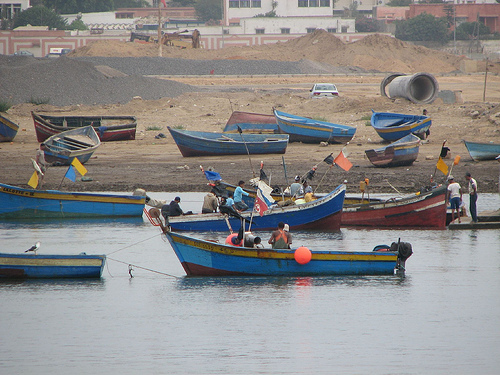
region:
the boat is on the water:
[158, 223, 411, 283]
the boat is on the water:
[2, 237, 107, 285]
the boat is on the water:
[1, 175, 154, 229]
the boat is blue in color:
[162, 226, 412, 288]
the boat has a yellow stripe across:
[165, 230, 400, 265]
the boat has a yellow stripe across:
[0, 252, 105, 268]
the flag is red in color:
[330, 148, 353, 170]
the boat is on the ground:
[165, 122, 290, 155]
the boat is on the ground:
[371, 108, 431, 140]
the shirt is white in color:
[447, 180, 462, 199]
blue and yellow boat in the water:
[149, 216, 431, 288]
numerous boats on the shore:
[3, 96, 499, 208]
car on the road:
[304, 70, 339, 103]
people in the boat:
[214, 211, 316, 263]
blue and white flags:
[53, 149, 100, 201]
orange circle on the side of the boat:
[292, 245, 322, 267]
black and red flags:
[319, 146, 358, 177]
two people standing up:
[443, 170, 485, 227]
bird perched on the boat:
[23, 237, 50, 265]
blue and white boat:
[5, 238, 110, 293]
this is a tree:
[26, 3, 66, 21]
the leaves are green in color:
[35, 6, 57, 23]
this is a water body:
[194, 271, 437, 369]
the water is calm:
[243, 308, 358, 355]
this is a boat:
[173, 237, 368, 294]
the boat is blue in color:
[241, 255, 268, 265]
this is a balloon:
[291, 242, 308, 267]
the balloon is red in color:
[297, 252, 307, 262]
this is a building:
[246, 13, 298, 38]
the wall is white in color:
[258, 17, 281, 23]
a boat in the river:
[147, 219, 414, 279]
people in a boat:
[162, 147, 344, 232]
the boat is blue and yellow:
[156, 225, 409, 284]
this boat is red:
[332, 169, 454, 235]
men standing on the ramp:
[440, 166, 481, 231]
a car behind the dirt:
[308, 79, 342, 100]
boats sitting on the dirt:
[7, 99, 497, 164]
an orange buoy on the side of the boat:
[292, 246, 314, 266]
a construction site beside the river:
[2, 24, 494, 139]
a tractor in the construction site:
[156, 27, 203, 53]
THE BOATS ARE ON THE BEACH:
[2, 92, 498, 187]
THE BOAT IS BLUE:
[156, 218, 416, 285]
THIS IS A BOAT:
[151, 215, 413, 285]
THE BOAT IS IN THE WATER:
[150, 223, 411, 293]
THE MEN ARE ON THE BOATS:
[144, 153, 326, 271]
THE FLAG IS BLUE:
[63, 167, 80, 190]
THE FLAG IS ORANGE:
[329, 147, 355, 177]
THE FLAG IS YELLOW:
[73, 154, 93, 182]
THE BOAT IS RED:
[336, 178, 456, 243]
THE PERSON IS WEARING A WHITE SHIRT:
[442, 174, 462, 208]